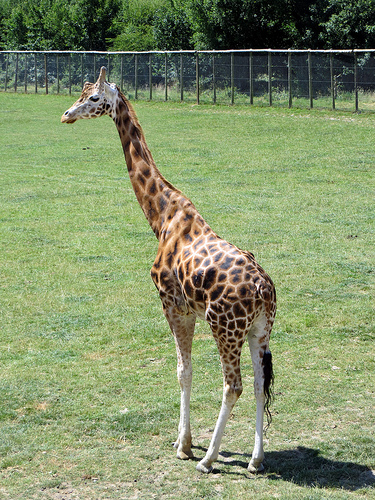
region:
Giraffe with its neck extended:
[59, 57, 297, 473]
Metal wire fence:
[2, 50, 372, 107]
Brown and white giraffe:
[61, 61, 283, 469]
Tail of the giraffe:
[253, 305, 275, 417]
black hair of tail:
[255, 352, 279, 418]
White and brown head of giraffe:
[60, 67, 121, 125]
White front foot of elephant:
[167, 357, 194, 454]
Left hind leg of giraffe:
[193, 381, 238, 465]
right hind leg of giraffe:
[244, 323, 262, 475]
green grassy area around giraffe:
[5, 90, 373, 491]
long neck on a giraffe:
[120, 103, 170, 218]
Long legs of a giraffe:
[151, 362, 289, 472]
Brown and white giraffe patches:
[169, 238, 235, 311]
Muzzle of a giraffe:
[57, 110, 75, 127]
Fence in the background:
[189, 63, 279, 96]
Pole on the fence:
[224, 67, 245, 103]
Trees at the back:
[139, 6, 330, 42]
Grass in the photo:
[51, 337, 144, 423]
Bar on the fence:
[95, 48, 180, 59]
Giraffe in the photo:
[54, 70, 292, 461]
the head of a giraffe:
[54, 27, 178, 138]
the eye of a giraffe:
[84, 88, 105, 110]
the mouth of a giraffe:
[55, 100, 82, 132]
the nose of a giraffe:
[56, 105, 78, 131]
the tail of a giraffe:
[246, 288, 289, 439]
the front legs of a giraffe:
[163, 272, 235, 467]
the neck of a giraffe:
[120, 107, 190, 298]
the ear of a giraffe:
[80, 56, 132, 102]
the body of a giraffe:
[120, 153, 311, 382]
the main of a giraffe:
[111, 75, 178, 294]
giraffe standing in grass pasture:
[54, 67, 295, 473]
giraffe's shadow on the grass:
[191, 439, 373, 486]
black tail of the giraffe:
[259, 347, 280, 430]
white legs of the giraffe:
[176, 369, 272, 452]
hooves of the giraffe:
[180, 439, 268, 473]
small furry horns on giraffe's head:
[96, 65, 109, 83]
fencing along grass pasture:
[1, 44, 371, 115]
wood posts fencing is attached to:
[1, 44, 367, 102]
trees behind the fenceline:
[1, 1, 374, 78]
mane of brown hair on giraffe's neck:
[113, 84, 183, 197]